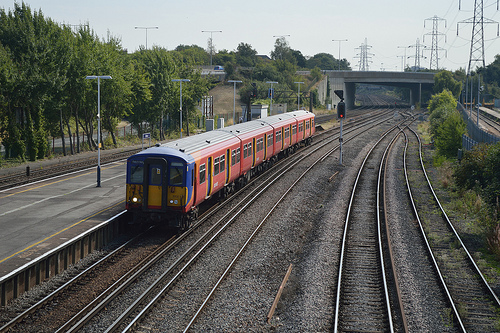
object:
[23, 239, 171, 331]
track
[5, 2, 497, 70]
sky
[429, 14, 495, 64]
clouds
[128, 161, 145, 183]
window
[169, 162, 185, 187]
window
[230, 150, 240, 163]
window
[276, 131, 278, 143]
window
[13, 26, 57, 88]
leaves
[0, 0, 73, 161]
trees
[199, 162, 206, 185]
window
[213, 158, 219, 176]
window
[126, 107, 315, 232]
railcar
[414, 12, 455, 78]
tower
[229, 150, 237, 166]
window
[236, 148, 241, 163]
window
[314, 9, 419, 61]
clouds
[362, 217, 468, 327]
track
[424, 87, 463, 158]
bushes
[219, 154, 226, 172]
window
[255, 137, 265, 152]
window